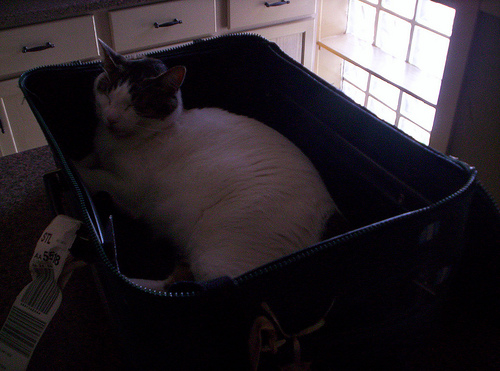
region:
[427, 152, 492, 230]
zipper around the suitcase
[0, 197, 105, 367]
white luggage tag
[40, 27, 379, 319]
white and black cat in a suitcase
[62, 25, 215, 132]
black cat ears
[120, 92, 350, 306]
white body of a cat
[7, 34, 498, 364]
black suitcase with a cat inside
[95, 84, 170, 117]
cat sleeping with its eyes closed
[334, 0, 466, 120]
window on the ground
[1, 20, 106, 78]
white drawers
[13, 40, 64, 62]
black handle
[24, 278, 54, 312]
Barcode on a pice of paper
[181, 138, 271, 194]
White fur of a cat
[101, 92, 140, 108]
Closed eyes of the cat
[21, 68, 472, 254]
Cat in a box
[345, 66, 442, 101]
Window with rectangular panels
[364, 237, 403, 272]
Blue side of the box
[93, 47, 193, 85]
Cat has two perked ears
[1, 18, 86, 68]
drawer behind the cat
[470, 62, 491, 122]
White wall beside the cat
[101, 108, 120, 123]
Nose of the cat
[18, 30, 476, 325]
cat laying in a suitcase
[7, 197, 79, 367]
baggage claim tag on the suitcase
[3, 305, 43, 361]
black and white lines of a barcode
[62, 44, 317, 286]
black and white cat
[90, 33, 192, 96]
two pointy ears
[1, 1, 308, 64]
row of three white drawers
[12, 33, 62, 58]
small black handle on the white drawer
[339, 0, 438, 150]
light coming in from the window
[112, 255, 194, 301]
jagged edge where the zipper runs along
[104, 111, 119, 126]
tiny nose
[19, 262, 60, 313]
a bar code on a white paper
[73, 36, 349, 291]
a cat lying in a box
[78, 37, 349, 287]
a white cat with dark patch on its head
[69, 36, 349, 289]
a cat with its eyes closed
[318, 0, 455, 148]
a window with light shining through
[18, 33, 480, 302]
a box on a counter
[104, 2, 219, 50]
a white drawer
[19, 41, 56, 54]
a handle on a drawer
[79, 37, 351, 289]
a cat with long whiskers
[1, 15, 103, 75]
a white drawer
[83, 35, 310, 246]
cat in plastic container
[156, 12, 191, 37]
black handle on drawer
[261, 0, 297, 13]
black handle on drawer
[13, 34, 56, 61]
black handle on drawer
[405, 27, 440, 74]
window pane on window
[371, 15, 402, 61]
window pane on window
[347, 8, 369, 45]
window pane on window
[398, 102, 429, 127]
window pane on window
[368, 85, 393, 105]
window pane on window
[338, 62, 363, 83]
window pane on window